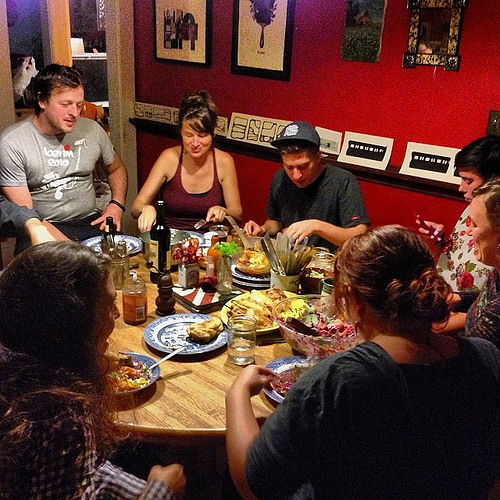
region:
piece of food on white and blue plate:
[142, 310, 232, 359]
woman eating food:
[221, 222, 498, 497]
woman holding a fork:
[130, 90, 243, 234]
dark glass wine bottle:
[148, 198, 172, 283]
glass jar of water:
[224, 313, 259, 366]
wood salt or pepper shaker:
[152, 272, 176, 315]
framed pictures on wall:
[149, 2, 296, 80]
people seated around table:
[0, 62, 496, 498]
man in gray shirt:
[2, 65, 129, 250]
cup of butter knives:
[259, 228, 316, 287]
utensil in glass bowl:
[274, 293, 354, 357]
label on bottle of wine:
[150, 197, 170, 280]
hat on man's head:
[272, 120, 321, 188]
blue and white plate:
[144, 312, 226, 355]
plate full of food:
[107, 352, 163, 399]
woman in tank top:
[134, 94, 240, 228]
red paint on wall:
[313, 88, 413, 108]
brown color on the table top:
[160, 399, 213, 424]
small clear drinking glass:
[216, 315, 265, 370]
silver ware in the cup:
[251, 228, 319, 281]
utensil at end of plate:
[142, 334, 197, 386]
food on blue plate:
[111, 360, 147, 393]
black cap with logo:
[268, 111, 343, 154]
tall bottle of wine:
[141, 193, 175, 274]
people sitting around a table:
[1, 60, 498, 498]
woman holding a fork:
[129, 89, 241, 228]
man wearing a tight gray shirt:
[0, 60, 128, 253]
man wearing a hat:
[240, 122, 370, 252]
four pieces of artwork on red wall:
[149, 0, 469, 78]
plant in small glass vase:
[211, 235, 239, 295]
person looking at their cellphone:
[417, 133, 499, 289]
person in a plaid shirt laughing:
[1, 241, 188, 498]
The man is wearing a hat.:
[268, 122, 367, 237]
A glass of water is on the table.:
[223, 310, 255, 365]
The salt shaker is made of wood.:
[151, 271, 182, 318]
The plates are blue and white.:
[145, 304, 230, 364]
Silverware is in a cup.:
[256, 232, 311, 291]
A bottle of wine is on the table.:
[150, 202, 174, 284]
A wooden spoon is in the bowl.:
[223, 213, 258, 258]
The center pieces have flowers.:
[211, 238, 241, 294]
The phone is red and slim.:
[408, 209, 442, 241]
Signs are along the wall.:
[338, 128, 398, 169]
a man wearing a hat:
[270, 108, 364, 199]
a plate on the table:
[159, 305, 222, 366]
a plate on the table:
[255, 342, 319, 437]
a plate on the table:
[110, 338, 195, 425]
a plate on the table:
[61, 218, 148, 273]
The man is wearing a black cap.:
[267, 116, 334, 148]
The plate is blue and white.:
[150, 308, 229, 354]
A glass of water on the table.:
[223, 313, 263, 368]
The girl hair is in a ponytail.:
[348, 248, 448, 325]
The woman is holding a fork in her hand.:
[181, 209, 245, 235]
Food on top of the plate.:
[115, 360, 151, 387]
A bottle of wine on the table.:
[143, 194, 179, 279]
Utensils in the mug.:
[267, 229, 309, 286]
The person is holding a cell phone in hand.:
[408, 209, 448, 247]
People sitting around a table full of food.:
[13, 60, 493, 492]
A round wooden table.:
[9, 213, 421, 450]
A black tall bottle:
[152, 195, 172, 282]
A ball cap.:
[270, 120, 324, 150]